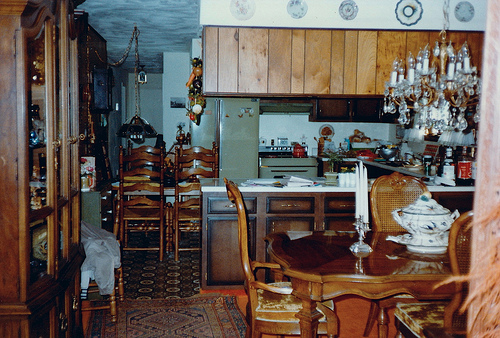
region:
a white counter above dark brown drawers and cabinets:
[198, 178, 475, 286]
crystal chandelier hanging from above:
[382, 0, 479, 135]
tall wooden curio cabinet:
[0, 0, 83, 335]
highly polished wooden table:
[265, 230, 472, 337]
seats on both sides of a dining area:
[108, 140, 219, 263]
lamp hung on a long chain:
[104, 25, 155, 142]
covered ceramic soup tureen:
[386, 190, 458, 254]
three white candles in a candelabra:
[348, 157, 372, 254]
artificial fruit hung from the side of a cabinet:
[185, 25, 217, 125]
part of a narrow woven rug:
[87, 292, 248, 336]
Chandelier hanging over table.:
[386, 0, 479, 135]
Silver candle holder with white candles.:
[345, 157, 381, 258]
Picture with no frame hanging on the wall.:
[164, 88, 188, 115]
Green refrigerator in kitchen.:
[187, 96, 259, 178]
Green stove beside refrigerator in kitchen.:
[260, 135, 319, 178]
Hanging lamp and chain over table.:
[95, 23, 158, 140]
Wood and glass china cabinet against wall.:
[0, 5, 84, 336]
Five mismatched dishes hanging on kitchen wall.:
[225, 0, 476, 27]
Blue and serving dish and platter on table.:
[386, 190, 462, 252]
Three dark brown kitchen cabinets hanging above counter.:
[312, 98, 410, 123]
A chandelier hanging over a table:
[382, 3, 487, 159]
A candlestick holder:
[345, 214, 374, 256]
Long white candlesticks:
[345, 148, 367, 216]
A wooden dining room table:
[258, 205, 470, 336]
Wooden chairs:
[111, 137, 219, 262]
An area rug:
[83, 285, 258, 333]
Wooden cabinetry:
[207, 96, 482, 276]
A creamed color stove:
[255, 140, 316, 181]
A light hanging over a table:
[113, 25, 160, 147]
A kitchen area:
[193, 57, 483, 286]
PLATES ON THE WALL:
[397, 4, 428, 21]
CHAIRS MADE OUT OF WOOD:
[184, 152, 213, 167]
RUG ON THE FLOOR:
[136, 299, 228, 336]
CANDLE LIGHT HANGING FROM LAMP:
[421, 61, 425, 72]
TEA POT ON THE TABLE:
[398, 195, 443, 258]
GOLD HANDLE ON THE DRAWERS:
[273, 203, 300, 208]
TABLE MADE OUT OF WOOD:
[317, 244, 340, 262]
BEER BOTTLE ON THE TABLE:
[458, 144, 469, 186]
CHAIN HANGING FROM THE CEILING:
[117, 37, 135, 63]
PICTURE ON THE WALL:
[167, 97, 191, 109]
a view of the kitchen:
[25, 39, 483, 330]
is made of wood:
[200, 25, 385, 91]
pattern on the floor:
[146, 270, 184, 296]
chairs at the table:
[220, 170, 431, 299]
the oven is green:
[253, 140, 320, 174]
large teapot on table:
[401, 213, 450, 260]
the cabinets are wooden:
[227, 190, 322, 227]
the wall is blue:
[130, 0, 181, 45]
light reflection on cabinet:
[202, 47, 269, 92]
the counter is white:
[235, 176, 347, 193]